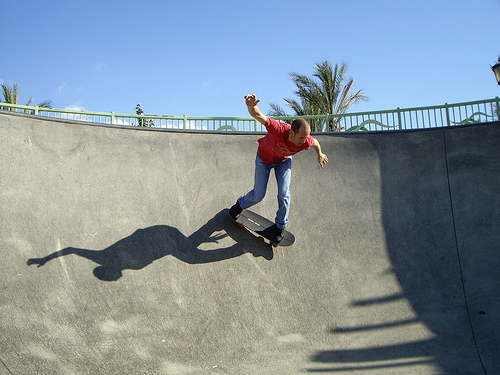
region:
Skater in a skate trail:
[215, 81, 339, 266]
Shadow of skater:
[18, 207, 223, 293]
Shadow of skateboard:
[216, 220, 285, 280]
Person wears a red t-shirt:
[213, 84, 340, 244]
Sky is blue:
[3, 3, 498, 97]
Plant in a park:
[281, 46, 377, 131]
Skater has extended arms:
[213, 81, 342, 260]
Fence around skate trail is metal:
[2, 95, 497, 128]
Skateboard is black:
[221, 200, 301, 257]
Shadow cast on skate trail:
[306, 111, 496, 373]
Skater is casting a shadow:
[12, 82, 345, 289]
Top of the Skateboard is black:
[210, 195, 316, 252]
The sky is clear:
[7, 8, 491, 116]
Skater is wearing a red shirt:
[244, 115, 341, 193]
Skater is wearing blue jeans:
[221, 134, 316, 257]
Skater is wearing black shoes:
[214, 186, 317, 261]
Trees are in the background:
[9, 48, 395, 128]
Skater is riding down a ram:
[189, 88, 347, 268]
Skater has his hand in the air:
[220, 86, 347, 175]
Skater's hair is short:
[278, 116, 333, 148]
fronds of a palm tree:
[290, 52, 365, 131]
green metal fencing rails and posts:
[105, 111, 240, 131]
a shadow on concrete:
[18, 199, 270, 274]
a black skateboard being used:
[226, 193, 298, 248]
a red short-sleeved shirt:
[255, 113, 287, 163]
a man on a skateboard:
[214, 85, 329, 260]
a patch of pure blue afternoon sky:
[137, 19, 247, 75]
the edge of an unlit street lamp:
[484, 53, 498, 90]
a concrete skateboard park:
[25, 129, 494, 374]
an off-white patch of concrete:
[90, 309, 149, 345]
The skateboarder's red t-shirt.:
[263, 120, 315, 172]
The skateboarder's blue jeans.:
[253, 158, 290, 243]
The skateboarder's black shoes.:
[233, 201, 287, 243]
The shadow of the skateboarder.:
[15, 227, 239, 277]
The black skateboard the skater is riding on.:
[231, 206, 298, 251]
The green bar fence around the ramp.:
[8, 100, 498, 125]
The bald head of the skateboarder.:
[288, 114, 313, 147]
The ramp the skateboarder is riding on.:
[8, 124, 498, 346]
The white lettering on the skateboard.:
[247, 213, 260, 229]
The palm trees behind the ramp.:
[1, 45, 383, 128]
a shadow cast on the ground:
[25, 206, 255, 292]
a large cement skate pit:
[324, 203, 464, 361]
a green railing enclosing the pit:
[139, 110, 239, 136]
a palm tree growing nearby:
[289, 62, 365, 128]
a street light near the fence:
[489, 59, 499, 90]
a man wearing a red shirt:
[232, 82, 322, 264]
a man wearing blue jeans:
[243, 104, 303, 245]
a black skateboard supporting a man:
[240, 213, 285, 256]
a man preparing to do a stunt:
[231, 76, 330, 265]